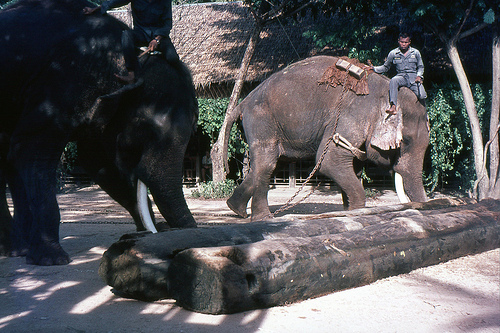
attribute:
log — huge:
[96, 195, 493, 315]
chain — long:
[264, 70, 356, 218]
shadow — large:
[1, 205, 269, 330]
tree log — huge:
[166, 199, 498, 316]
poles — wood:
[170, 192, 498, 300]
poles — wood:
[83, 202, 460, 292]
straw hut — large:
[180, 2, 252, 80]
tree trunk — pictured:
[429, 35, 499, 195]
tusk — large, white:
[119, 184, 197, 248]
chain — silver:
[58, 63, 352, 226]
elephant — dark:
[17, 8, 219, 228]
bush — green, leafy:
[425, 80, 481, 184]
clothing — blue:
[370, 49, 433, 109]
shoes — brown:
[379, 104, 400, 120]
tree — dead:
[204, 20, 254, 192]